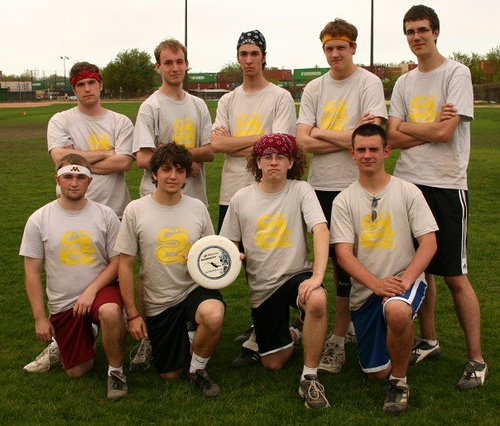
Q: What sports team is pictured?
A: Frisbee.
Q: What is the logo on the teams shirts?
A: Yellow Snake.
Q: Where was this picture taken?
A: On field.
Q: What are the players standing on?
A: Grass.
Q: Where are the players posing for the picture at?
A: The field.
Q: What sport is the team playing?
A: Frisbee.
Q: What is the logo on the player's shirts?
A: A yellow snake.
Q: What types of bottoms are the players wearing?
A: Shorts.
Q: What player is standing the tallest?
A: The player on the back right.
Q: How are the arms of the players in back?
A: Crossed.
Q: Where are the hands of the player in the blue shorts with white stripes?
A: On his knee.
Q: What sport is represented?
A: Frisbee.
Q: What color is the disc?
A: White.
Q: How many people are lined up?
A: 9.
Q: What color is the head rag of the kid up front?
A: Red.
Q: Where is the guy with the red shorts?
A: Left.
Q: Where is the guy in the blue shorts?
A: Right.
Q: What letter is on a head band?
A: M.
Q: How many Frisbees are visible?
A: 1.